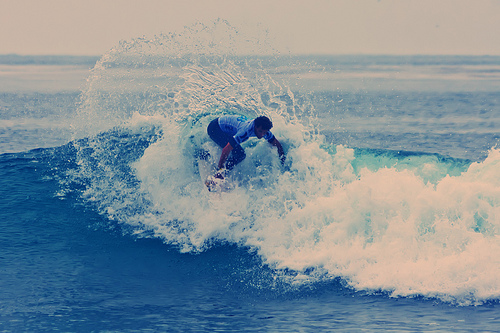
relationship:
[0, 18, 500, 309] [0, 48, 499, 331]
wave on ocean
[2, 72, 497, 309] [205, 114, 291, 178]
wave behind surfer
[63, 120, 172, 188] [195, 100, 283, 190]
wave behind surfer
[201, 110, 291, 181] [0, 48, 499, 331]
man in ocean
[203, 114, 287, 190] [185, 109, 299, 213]
man on surfboard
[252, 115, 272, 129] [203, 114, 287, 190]
hair of man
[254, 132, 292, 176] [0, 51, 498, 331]
arm in water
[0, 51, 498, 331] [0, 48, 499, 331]
water of ocean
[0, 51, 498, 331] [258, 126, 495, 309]
water form waves